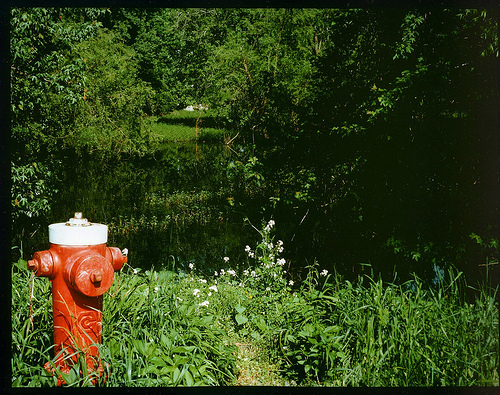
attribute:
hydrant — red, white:
[27, 205, 128, 386]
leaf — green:
[54, 77, 66, 93]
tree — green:
[9, 3, 76, 256]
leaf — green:
[19, 19, 32, 33]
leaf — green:
[58, 61, 74, 77]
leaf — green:
[85, 22, 96, 34]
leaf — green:
[18, 171, 32, 182]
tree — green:
[197, 35, 282, 148]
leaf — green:
[208, 71, 219, 79]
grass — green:
[29, 353, 130, 389]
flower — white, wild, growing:
[209, 283, 219, 293]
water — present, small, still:
[42, 153, 402, 277]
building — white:
[180, 101, 216, 111]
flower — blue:
[432, 261, 448, 282]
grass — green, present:
[406, 290, 465, 305]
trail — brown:
[226, 334, 282, 392]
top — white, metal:
[46, 209, 111, 249]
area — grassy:
[16, 253, 476, 377]